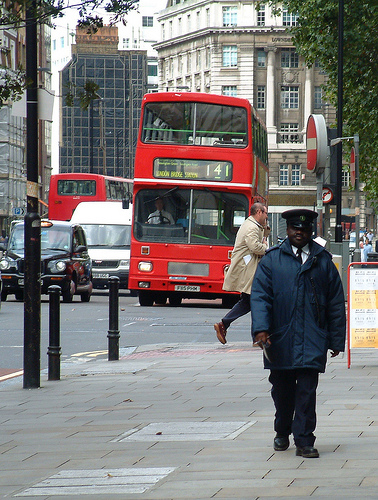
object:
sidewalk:
[99, 400, 262, 486]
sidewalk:
[78, 426, 211, 481]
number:
[206, 163, 229, 178]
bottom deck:
[128, 240, 222, 294]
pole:
[294, 132, 348, 254]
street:
[4, 286, 363, 378]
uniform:
[252, 238, 348, 459]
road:
[1, 294, 365, 381]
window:
[220, 45, 305, 110]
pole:
[313, 172, 330, 245]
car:
[0, 217, 90, 302]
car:
[68, 197, 138, 297]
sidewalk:
[1, 346, 362, 498]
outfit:
[250, 207, 346, 457]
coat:
[217, 209, 270, 298]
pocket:
[245, 257, 262, 268]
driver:
[148, 199, 176, 226]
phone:
[265, 217, 268, 226]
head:
[286, 214, 313, 247]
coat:
[251, 235, 347, 373]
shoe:
[212, 320, 228, 344]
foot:
[214, 319, 227, 345]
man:
[211, 202, 272, 343]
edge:
[306, 115, 317, 173]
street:
[1, 285, 255, 381]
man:
[145, 198, 175, 225]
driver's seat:
[139, 191, 184, 237]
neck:
[288, 241, 308, 251]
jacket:
[221, 215, 267, 296]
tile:
[119, 343, 261, 358]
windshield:
[116, 86, 275, 302]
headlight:
[134, 250, 230, 285]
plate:
[175, 286, 200, 291]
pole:
[15, 3, 48, 215]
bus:
[128, 92, 269, 305]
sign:
[300, 112, 338, 177]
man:
[251, 206, 346, 461]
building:
[150, 0, 351, 191]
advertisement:
[348, 268, 378, 350]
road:
[1, 296, 248, 380]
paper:
[243, 254, 252, 266]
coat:
[221, 216, 268, 298]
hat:
[281, 207, 319, 230]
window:
[143, 99, 258, 160]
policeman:
[244, 195, 352, 458]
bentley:
[0, 219, 93, 303]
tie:
[292, 248, 307, 263]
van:
[69, 199, 128, 297]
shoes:
[216, 321, 234, 344]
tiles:
[125, 348, 228, 357]